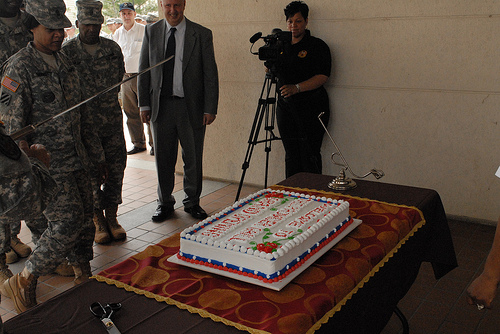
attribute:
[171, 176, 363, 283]
cake — red, white, decorated, rectangular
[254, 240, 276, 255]
flower — red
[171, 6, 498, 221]
wall — white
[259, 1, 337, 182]
woman — photographer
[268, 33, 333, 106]
shirt — black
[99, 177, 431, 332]
cloth — red, brown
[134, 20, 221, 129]
coat — grey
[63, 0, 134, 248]
soldier — american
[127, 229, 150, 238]
tile — ceramic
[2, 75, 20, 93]
flag — american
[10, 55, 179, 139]
blade — long